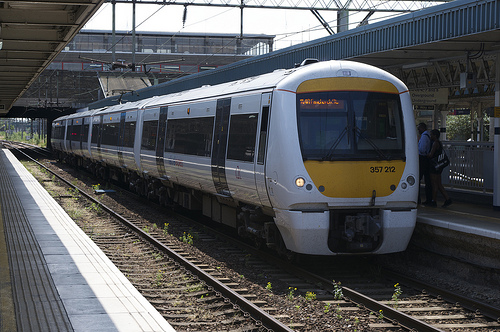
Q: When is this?
A: Daytime.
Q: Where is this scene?
A: The train station.